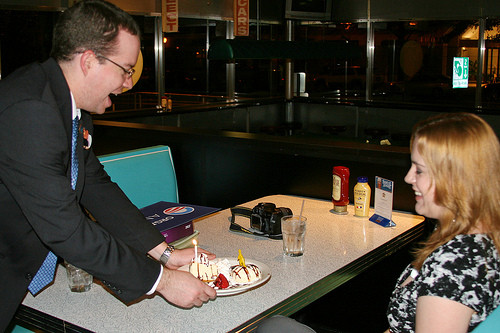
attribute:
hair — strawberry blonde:
[412, 107, 499, 271]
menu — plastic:
[367, 174, 392, 229]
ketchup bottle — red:
[329, 162, 351, 214]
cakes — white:
[189, 246, 317, 293]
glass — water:
[266, 206, 314, 253]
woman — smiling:
[381, 109, 496, 326]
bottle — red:
[332, 158, 352, 211]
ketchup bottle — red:
[321, 158, 353, 223]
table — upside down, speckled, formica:
[12, 190, 427, 331]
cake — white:
[187, 250, 219, 277]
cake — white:
[228, 261, 259, 290]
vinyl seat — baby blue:
[117, 154, 180, 199]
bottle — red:
[331, 166, 348, 211]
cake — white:
[181, 252, 226, 290]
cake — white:
[224, 250, 265, 288]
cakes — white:
[201, 252, 262, 297]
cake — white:
[187, 253, 219, 282]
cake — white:
[228, 260, 261, 285]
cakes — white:
[190, 260, 260, 286]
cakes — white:
[200, 250, 272, 301]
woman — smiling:
[255, 111, 498, 331]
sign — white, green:
[453, 57, 473, 92]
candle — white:
[178, 234, 208, 264]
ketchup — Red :
[327, 160, 351, 219]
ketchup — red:
[325, 164, 352, 209]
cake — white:
[187, 244, 258, 286]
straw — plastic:
[297, 200, 305, 220]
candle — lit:
[190, 236, 200, 262]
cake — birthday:
[185, 256, 225, 282]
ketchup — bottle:
[328, 163, 350, 217]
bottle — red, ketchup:
[328, 165, 351, 215]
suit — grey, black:
[0, 56, 165, 331]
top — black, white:
[384, 231, 481, 331]